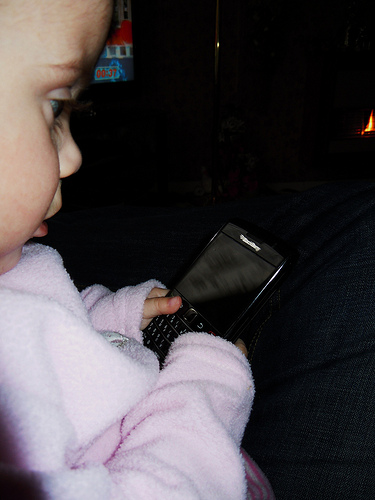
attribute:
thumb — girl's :
[140, 293, 182, 316]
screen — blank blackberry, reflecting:
[176, 235, 272, 322]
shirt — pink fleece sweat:
[3, 246, 262, 492]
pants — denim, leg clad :
[226, 477, 300, 498]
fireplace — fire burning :
[337, 111, 360, 149]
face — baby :
[5, 0, 112, 250]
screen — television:
[171, 231, 273, 323]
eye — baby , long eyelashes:
[45, 87, 73, 126]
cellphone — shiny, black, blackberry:
[139, 214, 283, 361]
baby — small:
[5, 9, 193, 497]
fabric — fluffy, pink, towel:
[3, 289, 144, 497]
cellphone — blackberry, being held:
[151, 215, 286, 358]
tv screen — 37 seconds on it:
[87, 61, 136, 86]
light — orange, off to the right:
[357, 99, 362, 142]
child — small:
[2, 7, 241, 444]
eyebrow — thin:
[47, 54, 95, 76]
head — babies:
[0, 11, 106, 277]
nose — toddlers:
[49, 114, 87, 184]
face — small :
[0, 4, 118, 286]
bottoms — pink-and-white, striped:
[235, 442, 269, 497]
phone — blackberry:
[155, 220, 278, 363]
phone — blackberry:
[144, 214, 281, 353]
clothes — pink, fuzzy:
[1, 248, 253, 498]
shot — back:
[6, 9, 352, 493]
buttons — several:
[152, 315, 183, 344]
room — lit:
[271, 67, 360, 466]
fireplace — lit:
[352, 101, 362, 129]